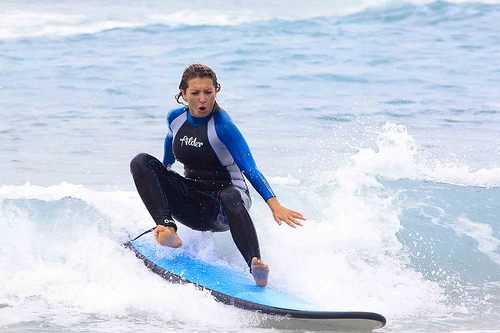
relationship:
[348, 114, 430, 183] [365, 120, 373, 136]
splash has part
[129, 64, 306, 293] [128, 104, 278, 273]
surfer has wetsuit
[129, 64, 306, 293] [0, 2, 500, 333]
surfer surfing in ocean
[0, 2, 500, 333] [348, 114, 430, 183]
ocean has splash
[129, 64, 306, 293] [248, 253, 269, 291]
surfer has foot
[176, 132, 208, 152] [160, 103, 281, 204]
writing on front of shirt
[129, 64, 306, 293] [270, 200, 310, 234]
surfer has hand